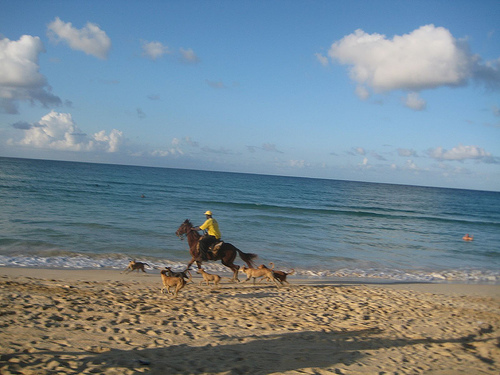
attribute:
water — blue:
[0, 154, 500, 280]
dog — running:
[196, 265, 225, 293]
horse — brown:
[156, 176, 279, 313]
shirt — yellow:
[198, 215, 223, 242]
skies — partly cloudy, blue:
[1, 0, 486, 191]